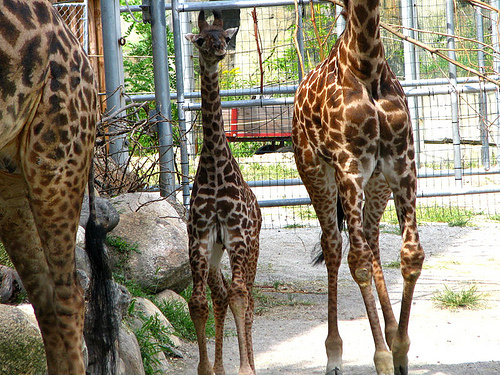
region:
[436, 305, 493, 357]
part of the white ground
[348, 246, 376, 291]
right knee of a giraffe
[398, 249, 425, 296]
left knee of a giraffe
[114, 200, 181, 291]
part of a stone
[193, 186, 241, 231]
chest of a small giraffe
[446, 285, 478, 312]
part of some grass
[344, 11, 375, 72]
neck of a giraffe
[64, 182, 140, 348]
tail of a giraffe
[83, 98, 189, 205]
part of some dry branches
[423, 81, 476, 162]
part of a meshed fence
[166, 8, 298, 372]
a baby giraffe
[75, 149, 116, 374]
a giraffe's long tail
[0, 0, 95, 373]
an adult sized giraffe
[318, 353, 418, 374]
a young giraffe's hooves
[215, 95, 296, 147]
a red trimmed wooden crate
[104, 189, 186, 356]
rock in the giraffe's enclosure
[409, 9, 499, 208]
a gray metal fence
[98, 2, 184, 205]
two gray metal poles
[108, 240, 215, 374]
patches of vegetation on the rocks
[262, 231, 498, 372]
a gravel walkway in the giraffe's enclosure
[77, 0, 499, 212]
a fence behind the giraffes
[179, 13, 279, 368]
a super cute baby giraffe walking by a bigger giraffe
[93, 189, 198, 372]
some rocks sitting on the ground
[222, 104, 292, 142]
a red bench on the other side of the fence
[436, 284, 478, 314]
a patch of grass on the ground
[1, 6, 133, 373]
the back legs of a giraffe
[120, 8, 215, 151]
a tree behind the fence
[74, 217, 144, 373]
the tail of a giraffe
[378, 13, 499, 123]
tree branches next to the giraffe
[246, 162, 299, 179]
some grass on the ground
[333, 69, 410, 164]
chest of a giraffe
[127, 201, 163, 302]
part of a stone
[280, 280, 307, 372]
part of the ground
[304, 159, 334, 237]
right hip of a giraffe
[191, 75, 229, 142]
neck of the small giraffe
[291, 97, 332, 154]
stomach of a giraffe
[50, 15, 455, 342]
baby giraffe and two adults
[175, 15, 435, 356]
baby giraffe as high as adult's body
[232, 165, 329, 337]
curve of baby giraffe equal to curve of adult's leg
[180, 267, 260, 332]
thick knobs at knee joint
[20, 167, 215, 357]
large rocks at side of giraffe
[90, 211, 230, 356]
weeds growing through weeds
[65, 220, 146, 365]
long strands of black hair on tail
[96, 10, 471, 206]
metal gate and fencing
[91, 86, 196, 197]
leafless branches behind rocks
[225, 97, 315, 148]
wooden cart on other side of fence